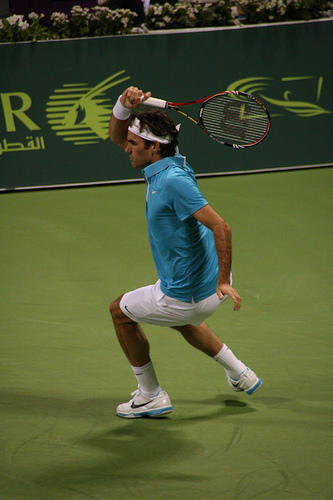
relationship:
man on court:
[105, 87, 264, 419] [18, 160, 318, 498]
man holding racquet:
[105, 104, 264, 419] [139, 88, 273, 152]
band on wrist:
[109, 95, 129, 122] [109, 95, 129, 124]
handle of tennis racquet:
[138, 91, 165, 106] [127, 89, 272, 148]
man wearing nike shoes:
[105, 104, 264, 419] [97, 362, 275, 432]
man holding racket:
[105, 104, 264, 419] [154, 80, 312, 151]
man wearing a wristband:
[105, 87, 264, 419] [109, 93, 133, 121]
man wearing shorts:
[105, 87, 264, 419] [118, 277, 233, 326]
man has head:
[105, 87, 264, 419] [121, 107, 176, 169]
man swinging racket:
[105, 87, 264, 419] [126, 90, 270, 149]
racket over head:
[126, 90, 270, 149] [121, 107, 176, 169]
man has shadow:
[105, 87, 264, 419] [62, 425, 206, 489]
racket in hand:
[139, 90, 270, 150] [116, 85, 149, 112]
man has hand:
[105, 104, 264, 419] [116, 85, 149, 112]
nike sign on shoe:
[225, 378, 249, 391] [226, 366, 262, 396]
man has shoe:
[105, 104, 264, 419] [226, 366, 262, 396]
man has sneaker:
[105, 104, 264, 419] [211, 364, 269, 403]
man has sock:
[105, 104, 264, 419] [125, 364, 157, 394]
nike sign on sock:
[134, 371, 143, 376] [125, 364, 157, 394]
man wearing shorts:
[105, 104, 264, 419] [112, 277, 229, 330]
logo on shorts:
[125, 306, 134, 316] [120, 276, 232, 331]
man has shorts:
[105, 104, 264, 419] [120, 276, 232, 331]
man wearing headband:
[105, 104, 264, 419] [126, 113, 184, 144]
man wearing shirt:
[105, 104, 264, 419] [133, 167, 221, 295]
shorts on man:
[117, 270, 232, 328] [105, 87, 264, 419]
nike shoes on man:
[115, 387, 172, 421] [105, 104, 264, 419]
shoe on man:
[228, 372, 263, 395] [105, 104, 264, 419]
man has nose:
[105, 87, 264, 419] [123, 146, 132, 155]